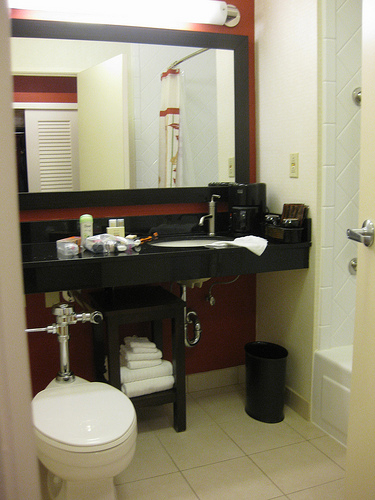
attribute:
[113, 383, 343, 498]
tiles — tan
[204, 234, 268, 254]
towel — Small , white 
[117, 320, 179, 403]
shelf — small, dark-brown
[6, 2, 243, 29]
light — metal , white , Long 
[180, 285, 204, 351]
pipe — silver 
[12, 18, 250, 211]
mirror — large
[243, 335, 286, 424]
trash can — black 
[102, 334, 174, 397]
towels — white 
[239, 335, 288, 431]
trash bin — black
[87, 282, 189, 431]
stool — black, small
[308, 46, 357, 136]
white tile — above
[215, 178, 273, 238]
coffee maker — Black , Small 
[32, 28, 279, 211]
mirror — large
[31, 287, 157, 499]
toilet — white , metal 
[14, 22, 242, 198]
mirror — Black 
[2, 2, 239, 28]
light fixture — oblong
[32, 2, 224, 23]
cover — white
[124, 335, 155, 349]
towel — white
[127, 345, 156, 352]
towel — white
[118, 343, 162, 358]
towel — white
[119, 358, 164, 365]
towel — white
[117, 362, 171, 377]
towel — white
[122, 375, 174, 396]
towel — white